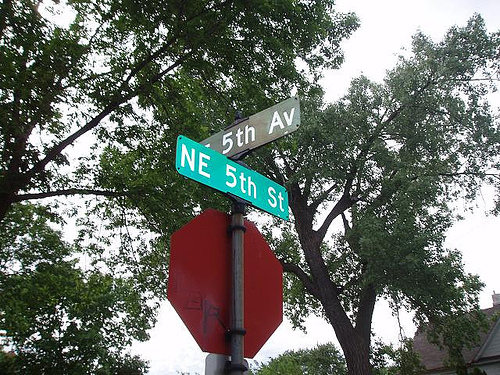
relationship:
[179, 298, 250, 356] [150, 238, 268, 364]
graffiti on back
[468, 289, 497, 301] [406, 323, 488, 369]
chimney on roof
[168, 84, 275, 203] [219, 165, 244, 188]
sign has number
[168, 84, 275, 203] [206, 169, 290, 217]
sign says 5th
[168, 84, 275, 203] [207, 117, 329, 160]
sign says 5th ave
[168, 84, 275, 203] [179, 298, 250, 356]
sign has graffiti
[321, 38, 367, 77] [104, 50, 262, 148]
light in trees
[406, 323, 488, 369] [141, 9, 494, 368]
roof behind tree